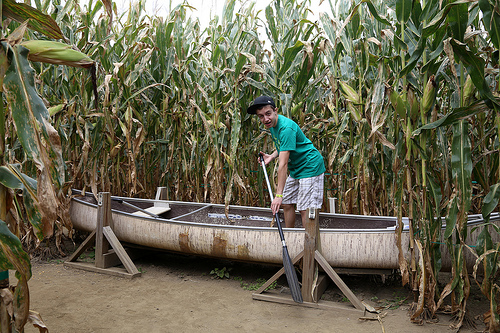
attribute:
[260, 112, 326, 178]
shirt — blue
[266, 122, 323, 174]
shirt — blue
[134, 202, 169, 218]
bench — white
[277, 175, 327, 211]
shorts — plaid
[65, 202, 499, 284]
boat field — WHITE, SMALL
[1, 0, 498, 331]
stalks — tall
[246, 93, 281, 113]
cap — black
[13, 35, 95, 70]
corn — EAR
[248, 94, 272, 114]
hat — black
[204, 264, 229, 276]
green plant — growing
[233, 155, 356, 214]
shorts — white, black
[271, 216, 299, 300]
tip — BLACK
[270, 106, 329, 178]
shirt — green 